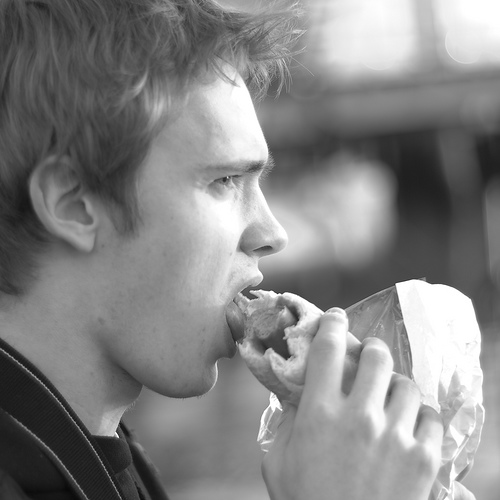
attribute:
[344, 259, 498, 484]
wrapper — plastic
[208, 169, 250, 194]
eye — open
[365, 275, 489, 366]
wrapper — plastic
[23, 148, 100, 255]
ear — human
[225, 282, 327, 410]
hotdog — partially eaten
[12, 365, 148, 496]
strap — black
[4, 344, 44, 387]
trim — WHITE